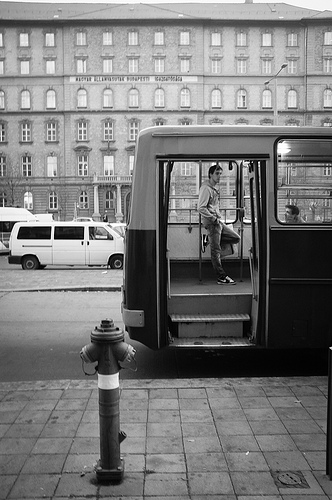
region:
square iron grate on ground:
[257, 465, 311, 497]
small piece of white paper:
[238, 446, 256, 458]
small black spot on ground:
[135, 465, 177, 487]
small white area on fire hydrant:
[83, 364, 143, 403]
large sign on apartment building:
[62, 66, 205, 81]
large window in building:
[74, 116, 104, 135]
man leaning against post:
[184, 163, 257, 301]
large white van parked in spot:
[8, 218, 125, 274]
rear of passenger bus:
[107, 102, 268, 372]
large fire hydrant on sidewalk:
[34, 312, 176, 490]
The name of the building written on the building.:
[65, 74, 195, 85]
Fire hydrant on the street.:
[71, 319, 149, 483]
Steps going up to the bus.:
[168, 257, 254, 342]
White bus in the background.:
[7, 217, 131, 272]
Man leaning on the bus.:
[196, 163, 251, 286]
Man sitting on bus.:
[277, 203, 306, 225]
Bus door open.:
[160, 164, 267, 347]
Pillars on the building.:
[89, 176, 126, 218]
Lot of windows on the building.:
[5, 23, 313, 217]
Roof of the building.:
[1, 2, 329, 33]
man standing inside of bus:
[196, 159, 250, 285]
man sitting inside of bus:
[280, 196, 307, 230]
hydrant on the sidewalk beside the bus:
[76, 310, 140, 485]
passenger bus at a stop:
[114, 176, 331, 362]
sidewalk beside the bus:
[1, 376, 331, 498]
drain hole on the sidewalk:
[267, 459, 309, 493]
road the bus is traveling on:
[2, 290, 326, 367]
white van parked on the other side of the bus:
[6, 215, 125, 271]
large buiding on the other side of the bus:
[0, 0, 330, 238]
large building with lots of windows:
[0, 0, 331, 251]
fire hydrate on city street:
[62, 309, 170, 490]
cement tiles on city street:
[160, 402, 301, 499]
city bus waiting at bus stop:
[120, 117, 317, 398]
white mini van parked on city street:
[1, 215, 139, 279]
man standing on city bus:
[189, 153, 249, 307]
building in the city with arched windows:
[2, 2, 213, 226]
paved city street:
[3, 281, 88, 413]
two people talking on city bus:
[178, 146, 331, 281]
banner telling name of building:
[63, 60, 207, 98]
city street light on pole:
[255, 59, 304, 134]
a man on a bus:
[181, 156, 272, 294]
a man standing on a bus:
[187, 170, 253, 300]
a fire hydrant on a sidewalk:
[45, 302, 199, 496]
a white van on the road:
[8, 205, 151, 279]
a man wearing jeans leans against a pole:
[185, 163, 266, 284]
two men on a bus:
[194, 162, 323, 280]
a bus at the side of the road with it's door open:
[94, 97, 331, 376]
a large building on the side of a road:
[19, 8, 328, 295]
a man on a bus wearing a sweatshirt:
[185, 157, 267, 288]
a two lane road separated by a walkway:
[0, 213, 329, 395]